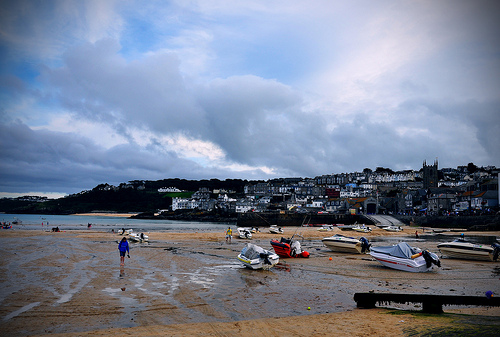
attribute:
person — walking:
[113, 234, 131, 259]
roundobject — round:
[328, 255, 333, 262]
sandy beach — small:
[5, 215, 499, 335]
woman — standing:
[118, 237, 130, 261]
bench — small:
[346, 273, 498, 333]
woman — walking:
[118, 236, 130, 265]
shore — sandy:
[1, 224, 498, 334]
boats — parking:
[239, 239, 275, 280]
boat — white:
[370, 237, 467, 278]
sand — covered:
[3, 224, 486, 321]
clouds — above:
[2, 0, 497, 195]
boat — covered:
[372, 239, 452, 273]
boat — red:
[373, 239, 442, 271]